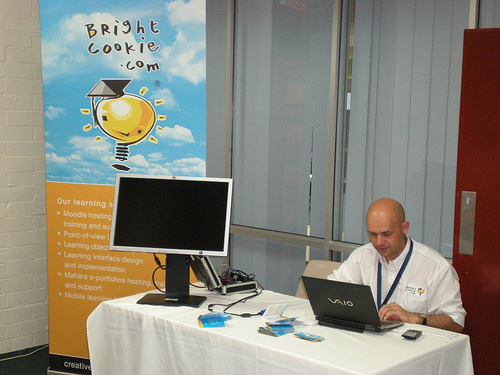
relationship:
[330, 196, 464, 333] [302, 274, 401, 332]
man working on laptop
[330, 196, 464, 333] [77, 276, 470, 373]
man sitting at table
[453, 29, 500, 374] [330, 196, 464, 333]
door behind man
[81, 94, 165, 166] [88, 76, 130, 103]
light bulb logo has graduation cap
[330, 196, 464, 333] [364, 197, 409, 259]
man has head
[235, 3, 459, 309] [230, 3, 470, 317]
blinds covering window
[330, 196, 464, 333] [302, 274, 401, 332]
man using laptop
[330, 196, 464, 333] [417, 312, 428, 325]
man wearing watch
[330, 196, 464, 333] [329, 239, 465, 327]
man wearing shirt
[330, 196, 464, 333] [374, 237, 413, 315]
man wearing ribbon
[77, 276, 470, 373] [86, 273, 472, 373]
table has table cloth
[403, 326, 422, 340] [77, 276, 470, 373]
cell phone on table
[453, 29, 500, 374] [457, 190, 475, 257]
door has handle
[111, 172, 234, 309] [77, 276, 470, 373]
monitor on table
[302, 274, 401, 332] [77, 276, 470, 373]
laptop on table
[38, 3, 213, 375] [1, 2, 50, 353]
bright cookie.com ad against wall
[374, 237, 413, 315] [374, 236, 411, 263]
ribbon on neck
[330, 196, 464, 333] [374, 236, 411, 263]
man has neck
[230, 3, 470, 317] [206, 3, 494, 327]
window on wall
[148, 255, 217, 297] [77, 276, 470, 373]
cord on table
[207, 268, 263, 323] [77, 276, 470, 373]
cord on table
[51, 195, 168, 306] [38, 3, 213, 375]
words on bright cookie.com ad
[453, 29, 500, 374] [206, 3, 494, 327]
door on wall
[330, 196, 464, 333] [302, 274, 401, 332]
man on laptop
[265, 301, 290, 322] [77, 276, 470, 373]
brochure on table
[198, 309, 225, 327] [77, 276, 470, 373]
brochure on table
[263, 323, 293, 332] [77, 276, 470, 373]
brochure on table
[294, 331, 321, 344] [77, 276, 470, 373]
brochure on table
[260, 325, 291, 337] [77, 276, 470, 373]
brochure on table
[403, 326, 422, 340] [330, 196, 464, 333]
cell phone of man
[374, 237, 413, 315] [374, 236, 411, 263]
ribbon around neck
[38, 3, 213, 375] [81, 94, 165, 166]
bright cookie.com ad has light bulb logo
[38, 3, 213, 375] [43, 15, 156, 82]
bright cookie.com ad has cloud logo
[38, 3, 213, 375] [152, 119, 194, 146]
bright cookie.com ad has cloud logo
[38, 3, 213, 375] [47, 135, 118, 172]
bright cookie.com ad has cloud logo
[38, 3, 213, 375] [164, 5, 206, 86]
bright cookie.com ad has cloud logo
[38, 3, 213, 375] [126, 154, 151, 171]
bright cookie.com ad has cloud logo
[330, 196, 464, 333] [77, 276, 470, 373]
man at table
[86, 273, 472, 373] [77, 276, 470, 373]
table cloth on table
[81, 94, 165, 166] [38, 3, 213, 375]
light bulb logo on bright cookie.com ad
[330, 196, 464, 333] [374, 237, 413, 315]
man has ribbon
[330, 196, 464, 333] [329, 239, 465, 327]
man has shirt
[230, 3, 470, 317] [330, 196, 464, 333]
window behind man